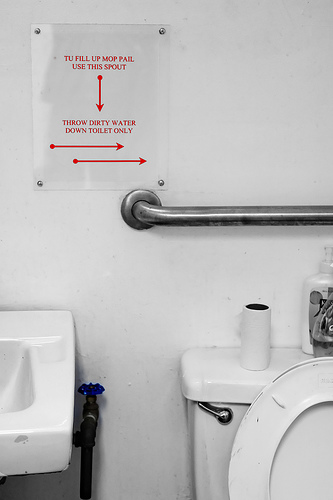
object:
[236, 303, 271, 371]
roll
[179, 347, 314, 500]
toilet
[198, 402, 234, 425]
flusher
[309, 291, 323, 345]
bottle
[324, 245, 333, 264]
pump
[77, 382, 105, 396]
handle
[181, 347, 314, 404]
lid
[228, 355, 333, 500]
seat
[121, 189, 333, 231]
bar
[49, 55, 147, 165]
instructions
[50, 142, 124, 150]
arrow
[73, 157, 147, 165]
arrow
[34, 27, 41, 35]
bolt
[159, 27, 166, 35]
bolt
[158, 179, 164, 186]
bolt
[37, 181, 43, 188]
bolt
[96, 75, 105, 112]
arrow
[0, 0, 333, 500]
wall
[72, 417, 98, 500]
pipe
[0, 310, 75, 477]
sink